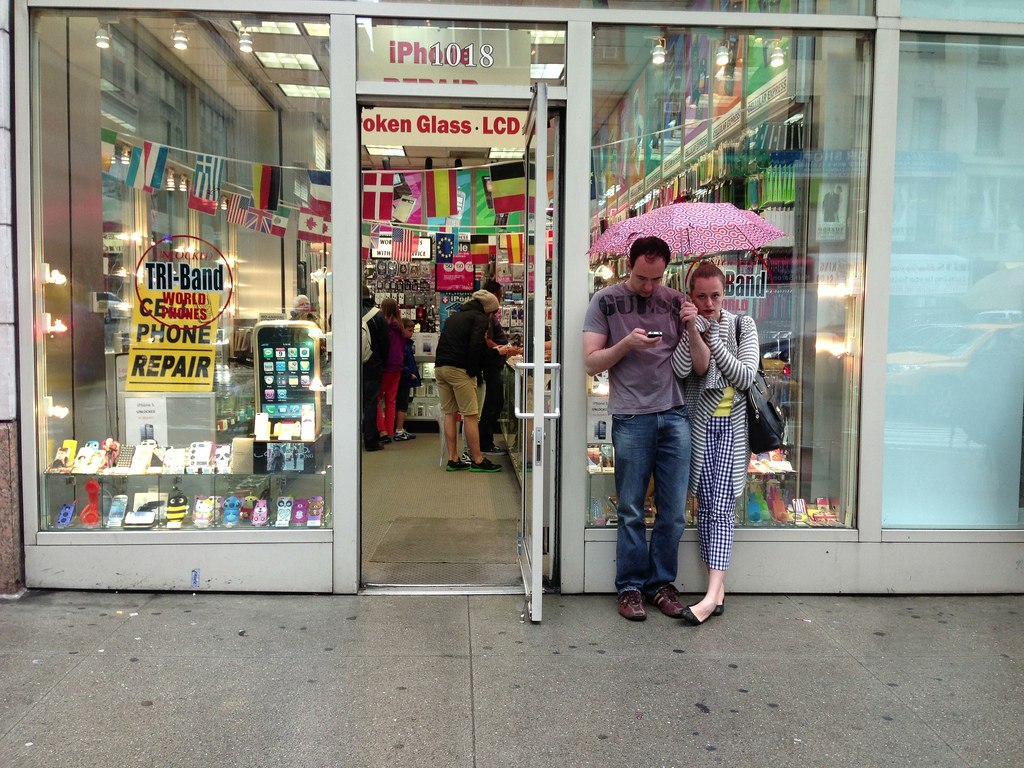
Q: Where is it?
A: This is at the store.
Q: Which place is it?
A: It is a store.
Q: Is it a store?
A: Yes, it is a store.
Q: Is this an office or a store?
A: It is a store.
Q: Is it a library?
A: No, it is a store.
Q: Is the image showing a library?
A: No, the picture is showing a store.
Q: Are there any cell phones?
A: Yes, there is a cell phone.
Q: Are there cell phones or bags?
A: Yes, there is a cell phone.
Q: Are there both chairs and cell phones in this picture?
A: No, there is a cell phone but no chairs.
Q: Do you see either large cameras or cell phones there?
A: Yes, there is a large cell phone.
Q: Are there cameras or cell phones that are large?
A: Yes, the cell phone is large.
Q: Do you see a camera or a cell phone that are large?
A: Yes, the cell phone is large.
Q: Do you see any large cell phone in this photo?
A: Yes, there is a large cell phone.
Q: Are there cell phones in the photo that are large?
A: Yes, there is a large cell phone.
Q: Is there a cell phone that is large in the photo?
A: Yes, there is a large cell phone.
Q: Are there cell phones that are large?
A: Yes, there is a cell phone that is large.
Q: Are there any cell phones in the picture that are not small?
A: Yes, there is a large cell phone.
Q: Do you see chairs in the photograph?
A: No, there are no chairs.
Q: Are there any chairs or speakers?
A: No, there are no chairs or speakers.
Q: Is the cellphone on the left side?
A: Yes, the cellphone is on the left of the image.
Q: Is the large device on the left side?
A: Yes, the cellphone is on the left of the image.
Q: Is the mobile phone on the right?
A: No, the mobile phone is on the left of the image.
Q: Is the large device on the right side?
A: No, the mobile phone is on the left of the image.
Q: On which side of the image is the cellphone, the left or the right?
A: The cellphone is on the left of the image.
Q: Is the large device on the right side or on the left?
A: The cellphone is on the left of the image.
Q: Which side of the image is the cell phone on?
A: The cell phone is on the left of the image.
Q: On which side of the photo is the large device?
A: The cell phone is on the left of the image.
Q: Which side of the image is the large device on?
A: The cell phone is on the left of the image.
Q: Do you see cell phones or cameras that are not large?
A: No, there is a cell phone but it is large.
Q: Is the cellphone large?
A: Yes, the cellphone is large.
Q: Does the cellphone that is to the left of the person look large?
A: Yes, the cell phone is large.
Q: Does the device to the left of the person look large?
A: Yes, the cell phone is large.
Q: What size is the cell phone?
A: The cell phone is large.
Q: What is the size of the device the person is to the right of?
A: The cell phone is large.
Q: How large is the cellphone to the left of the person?
A: The mobile phone is large.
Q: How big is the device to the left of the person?
A: The mobile phone is large.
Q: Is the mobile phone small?
A: No, the mobile phone is large.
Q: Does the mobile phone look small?
A: No, the mobile phone is large.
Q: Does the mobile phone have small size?
A: No, the mobile phone is large.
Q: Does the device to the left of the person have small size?
A: No, the mobile phone is large.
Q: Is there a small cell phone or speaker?
A: No, there is a cell phone but it is large.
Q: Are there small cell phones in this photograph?
A: No, there is a cell phone but it is large.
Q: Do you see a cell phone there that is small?
A: No, there is a cell phone but it is large.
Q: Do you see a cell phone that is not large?
A: No, there is a cell phone but it is large.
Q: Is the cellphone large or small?
A: The cellphone is large.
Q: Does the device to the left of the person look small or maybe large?
A: The cellphone is large.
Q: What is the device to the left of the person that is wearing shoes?
A: The device is a cell phone.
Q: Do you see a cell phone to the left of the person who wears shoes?
A: Yes, there is a cell phone to the left of the person.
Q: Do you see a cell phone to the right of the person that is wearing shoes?
A: No, the cell phone is to the left of the person.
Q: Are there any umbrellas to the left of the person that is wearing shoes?
A: No, there is a cell phone to the left of the person.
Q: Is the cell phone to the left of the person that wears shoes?
A: Yes, the cell phone is to the left of the person.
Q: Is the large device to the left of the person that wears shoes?
A: Yes, the cell phone is to the left of the person.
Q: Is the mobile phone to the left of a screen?
A: No, the mobile phone is to the left of the person.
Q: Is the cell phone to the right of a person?
A: No, the cell phone is to the left of a person.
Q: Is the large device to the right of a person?
A: No, the cell phone is to the left of a person.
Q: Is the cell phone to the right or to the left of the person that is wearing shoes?
A: The cell phone is to the left of the person.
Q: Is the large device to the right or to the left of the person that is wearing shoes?
A: The cell phone is to the left of the person.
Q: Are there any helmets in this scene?
A: No, there are no helmets.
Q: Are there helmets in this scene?
A: No, there are no helmets.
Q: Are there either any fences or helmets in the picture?
A: No, there are no helmets or fences.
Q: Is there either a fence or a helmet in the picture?
A: No, there are no helmets or fences.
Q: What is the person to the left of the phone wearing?
A: The person is wearing shoes.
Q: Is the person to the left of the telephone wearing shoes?
A: Yes, the person is wearing shoes.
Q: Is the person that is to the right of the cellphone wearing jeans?
A: No, the person is wearing shoes.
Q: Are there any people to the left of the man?
A: Yes, there is a person to the left of the man.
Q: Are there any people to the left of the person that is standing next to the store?
A: Yes, there is a person to the left of the man.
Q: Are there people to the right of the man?
A: No, the person is to the left of the man.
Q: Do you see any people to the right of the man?
A: No, the person is to the left of the man.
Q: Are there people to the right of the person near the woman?
A: No, the person is to the left of the man.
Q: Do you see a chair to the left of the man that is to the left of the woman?
A: No, there is a person to the left of the man.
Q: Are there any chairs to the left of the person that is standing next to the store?
A: No, there is a person to the left of the man.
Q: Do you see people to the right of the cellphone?
A: Yes, there is a person to the right of the cellphone.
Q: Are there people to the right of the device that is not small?
A: Yes, there is a person to the right of the cellphone.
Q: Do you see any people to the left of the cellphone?
A: No, the person is to the right of the cellphone.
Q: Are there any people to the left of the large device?
A: No, the person is to the right of the cellphone.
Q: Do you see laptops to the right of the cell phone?
A: No, there is a person to the right of the cell phone.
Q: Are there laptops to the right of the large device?
A: No, there is a person to the right of the cell phone.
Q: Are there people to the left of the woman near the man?
A: Yes, there is a person to the left of the woman.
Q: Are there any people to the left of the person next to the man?
A: Yes, there is a person to the left of the woman.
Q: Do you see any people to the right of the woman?
A: No, the person is to the left of the woman.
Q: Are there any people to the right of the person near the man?
A: No, the person is to the left of the woman.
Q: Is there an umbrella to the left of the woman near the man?
A: No, there is a person to the left of the woman.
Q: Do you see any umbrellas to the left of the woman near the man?
A: No, there is a person to the left of the woman.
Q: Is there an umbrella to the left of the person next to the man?
A: No, there is a person to the left of the woman.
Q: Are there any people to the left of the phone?
A: Yes, there is a person to the left of the phone.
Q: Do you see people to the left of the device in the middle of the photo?
A: Yes, there is a person to the left of the phone.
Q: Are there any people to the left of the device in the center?
A: Yes, there is a person to the left of the phone.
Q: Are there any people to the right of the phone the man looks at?
A: No, the person is to the left of the phone.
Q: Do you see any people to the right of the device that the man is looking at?
A: No, the person is to the left of the phone.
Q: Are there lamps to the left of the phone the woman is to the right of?
A: No, there is a person to the left of the phone.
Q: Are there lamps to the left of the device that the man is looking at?
A: No, there is a person to the left of the phone.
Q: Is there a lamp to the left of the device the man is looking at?
A: No, there is a person to the left of the phone.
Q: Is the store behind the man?
A: Yes, the store is behind the man.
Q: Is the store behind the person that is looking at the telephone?
A: Yes, the store is behind the man.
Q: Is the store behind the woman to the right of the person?
A: Yes, the store is behind the woman.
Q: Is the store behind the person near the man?
A: Yes, the store is behind the woman.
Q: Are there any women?
A: Yes, there is a woman.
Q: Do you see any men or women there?
A: Yes, there is a woman.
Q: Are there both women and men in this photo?
A: Yes, there are both a woman and men.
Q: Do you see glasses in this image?
A: No, there are no glasses.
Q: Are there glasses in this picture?
A: No, there are no glasses.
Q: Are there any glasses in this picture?
A: No, there are no glasses.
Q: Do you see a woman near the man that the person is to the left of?
A: Yes, there is a woman near the man.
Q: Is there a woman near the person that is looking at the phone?
A: Yes, there is a woman near the man.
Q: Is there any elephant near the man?
A: No, there is a woman near the man.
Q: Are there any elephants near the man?
A: No, there is a woman near the man.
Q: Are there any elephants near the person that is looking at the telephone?
A: No, there is a woman near the man.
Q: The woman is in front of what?
A: The woman is in front of the store.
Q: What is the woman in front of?
A: The woman is in front of the store.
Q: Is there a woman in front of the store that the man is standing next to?
A: Yes, there is a woman in front of the store.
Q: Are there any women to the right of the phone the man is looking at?
A: Yes, there is a woman to the right of the telephone.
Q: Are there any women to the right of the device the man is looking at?
A: Yes, there is a woman to the right of the telephone.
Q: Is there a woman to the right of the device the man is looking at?
A: Yes, there is a woman to the right of the telephone.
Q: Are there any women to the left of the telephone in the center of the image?
A: No, the woman is to the right of the phone.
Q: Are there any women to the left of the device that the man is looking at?
A: No, the woman is to the right of the phone.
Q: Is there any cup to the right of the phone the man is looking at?
A: No, there is a woman to the right of the phone.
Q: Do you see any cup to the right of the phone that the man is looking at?
A: No, there is a woman to the right of the phone.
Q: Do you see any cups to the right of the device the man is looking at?
A: No, there is a woman to the right of the phone.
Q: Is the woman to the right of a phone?
A: Yes, the woman is to the right of a phone.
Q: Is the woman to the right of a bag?
A: No, the woman is to the right of a phone.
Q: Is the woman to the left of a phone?
A: No, the woman is to the right of a phone.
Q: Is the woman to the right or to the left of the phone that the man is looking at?
A: The woman is to the right of the telephone.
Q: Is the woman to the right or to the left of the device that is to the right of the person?
A: The woman is to the right of the telephone.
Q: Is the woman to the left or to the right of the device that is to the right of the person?
A: The woman is to the right of the telephone.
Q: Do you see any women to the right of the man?
A: Yes, there is a woman to the right of the man.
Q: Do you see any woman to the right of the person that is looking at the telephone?
A: Yes, there is a woman to the right of the man.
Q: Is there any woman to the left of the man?
A: No, the woman is to the right of the man.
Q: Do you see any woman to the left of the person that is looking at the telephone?
A: No, the woman is to the right of the man.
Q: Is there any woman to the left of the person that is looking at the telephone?
A: No, the woman is to the right of the man.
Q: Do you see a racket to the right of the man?
A: No, there is a woman to the right of the man.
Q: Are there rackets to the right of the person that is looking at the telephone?
A: No, there is a woman to the right of the man.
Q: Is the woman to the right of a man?
A: Yes, the woman is to the right of a man.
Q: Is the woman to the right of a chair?
A: No, the woman is to the right of a man.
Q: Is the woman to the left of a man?
A: No, the woman is to the right of a man.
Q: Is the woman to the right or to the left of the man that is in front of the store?
A: The woman is to the right of the man.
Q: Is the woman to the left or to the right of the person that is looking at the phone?
A: The woman is to the right of the man.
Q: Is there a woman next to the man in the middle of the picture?
A: Yes, there is a woman next to the man.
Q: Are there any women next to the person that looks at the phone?
A: Yes, there is a woman next to the man.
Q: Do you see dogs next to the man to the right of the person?
A: No, there is a woman next to the man.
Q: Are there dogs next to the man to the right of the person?
A: No, there is a woman next to the man.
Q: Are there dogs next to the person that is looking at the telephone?
A: No, there is a woman next to the man.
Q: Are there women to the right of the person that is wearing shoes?
A: Yes, there is a woman to the right of the person.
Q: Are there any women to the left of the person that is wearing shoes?
A: No, the woman is to the right of the person.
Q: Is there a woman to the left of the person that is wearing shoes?
A: No, the woman is to the right of the person.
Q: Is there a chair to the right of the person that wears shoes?
A: No, there is a woman to the right of the person.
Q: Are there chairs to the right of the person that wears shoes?
A: No, there is a woman to the right of the person.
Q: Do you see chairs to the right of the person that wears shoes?
A: No, there is a woman to the right of the person.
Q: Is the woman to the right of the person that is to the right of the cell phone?
A: Yes, the woman is to the right of the person.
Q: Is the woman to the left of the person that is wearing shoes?
A: No, the woman is to the right of the person.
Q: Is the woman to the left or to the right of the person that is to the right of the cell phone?
A: The woman is to the right of the person.